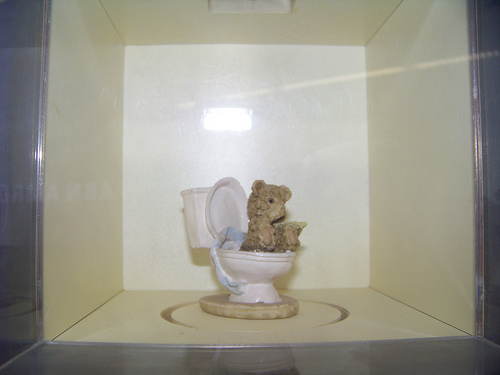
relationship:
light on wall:
[193, 101, 263, 136] [1, 2, 478, 367]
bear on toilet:
[240, 179, 308, 255] [169, 171, 301, 308]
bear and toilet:
[240, 179, 308, 255] [169, 171, 301, 308]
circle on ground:
[155, 289, 360, 333] [59, 275, 469, 351]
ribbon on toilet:
[201, 221, 256, 296] [169, 171, 301, 308]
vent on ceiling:
[202, 2, 297, 20] [79, 2, 402, 56]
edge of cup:
[293, 219, 306, 229] [287, 216, 309, 235]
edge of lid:
[293, 219, 306, 229] [202, 172, 246, 237]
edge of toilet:
[293, 219, 306, 229] [169, 171, 301, 308]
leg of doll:
[244, 226, 278, 250] [240, 172, 316, 258]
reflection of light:
[190, 95, 259, 136] [193, 101, 263, 136]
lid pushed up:
[202, 172, 246, 237] [198, 174, 260, 240]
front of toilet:
[272, 249, 296, 302] [169, 171, 301, 308]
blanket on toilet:
[209, 219, 257, 294] [169, 171, 301, 308]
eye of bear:
[261, 196, 283, 208] [240, 179, 308, 255]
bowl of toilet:
[222, 238, 296, 264] [169, 171, 301, 308]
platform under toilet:
[200, 292, 305, 319] [169, 171, 301, 308]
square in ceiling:
[208, 0, 299, 25] [79, 2, 402, 56]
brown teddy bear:
[239, 172, 312, 256] [240, 179, 308, 255]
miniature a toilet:
[177, 172, 299, 301] [169, 171, 301, 308]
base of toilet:
[197, 287, 309, 321] [169, 171, 301, 308]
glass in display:
[46, 4, 477, 352] [15, 0, 491, 364]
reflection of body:
[190, 95, 259, 136] [246, 174, 304, 260]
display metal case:
[15, 0, 491, 364] [18, 1, 487, 374]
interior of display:
[124, 47, 385, 288] [15, 0, 491, 364]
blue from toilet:
[206, 224, 255, 292] [169, 171, 301, 308]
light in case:
[193, 101, 263, 136] [18, 1, 487, 374]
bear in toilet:
[240, 179, 308, 255] [169, 171, 301, 308]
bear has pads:
[240, 179, 308, 255] [256, 226, 304, 249]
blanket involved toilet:
[209, 219, 257, 294] [169, 171, 301, 308]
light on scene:
[193, 101, 263, 136] [39, 5, 481, 354]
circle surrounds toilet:
[155, 289, 360, 333] [169, 171, 301, 308]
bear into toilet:
[240, 179, 308, 255] [169, 171, 301, 308]